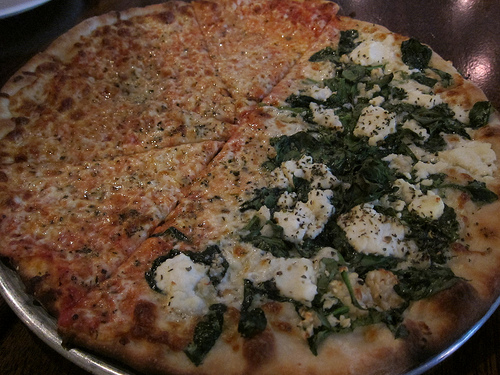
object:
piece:
[281, 132, 497, 299]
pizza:
[239, 15, 280, 69]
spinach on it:
[335, 63, 365, 102]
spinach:
[342, 64, 368, 82]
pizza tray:
[0, 266, 500, 375]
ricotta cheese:
[222, 244, 316, 300]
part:
[52, 43, 69, 62]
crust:
[46, 18, 92, 58]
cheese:
[237, 21, 276, 60]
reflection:
[456, 51, 496, 90]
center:
[212, 95, 263, 143]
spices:
[361, 105, 395, 134]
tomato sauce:
[56, 267, 89, 328]